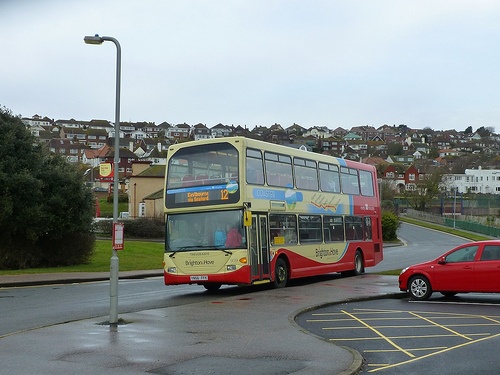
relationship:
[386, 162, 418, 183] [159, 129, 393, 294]
house behind bus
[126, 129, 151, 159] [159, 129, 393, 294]
house behind bus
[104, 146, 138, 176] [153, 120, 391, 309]
houses behind bus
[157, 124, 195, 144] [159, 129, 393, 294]
house behind bus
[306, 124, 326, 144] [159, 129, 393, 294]
house behind bus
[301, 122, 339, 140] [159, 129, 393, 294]
house behind bus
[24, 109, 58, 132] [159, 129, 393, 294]
house behind bus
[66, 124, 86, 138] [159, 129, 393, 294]
house behind bus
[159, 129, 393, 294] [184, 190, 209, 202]
bus has number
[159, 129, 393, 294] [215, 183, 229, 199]
bus has route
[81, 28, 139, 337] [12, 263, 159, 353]
pole lamp on street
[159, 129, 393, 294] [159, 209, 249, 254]
bus has window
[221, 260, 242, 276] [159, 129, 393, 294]
light front bus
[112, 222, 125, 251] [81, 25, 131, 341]
sign on pole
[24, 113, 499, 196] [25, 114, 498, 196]
houses on hill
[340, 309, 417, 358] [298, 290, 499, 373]
line on pavement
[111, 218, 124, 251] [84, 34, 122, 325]
sign attached to pole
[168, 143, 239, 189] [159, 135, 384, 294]
window on bus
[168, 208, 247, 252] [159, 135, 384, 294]
window on bus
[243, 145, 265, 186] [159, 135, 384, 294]
window on bus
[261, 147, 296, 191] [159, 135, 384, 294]
window on bus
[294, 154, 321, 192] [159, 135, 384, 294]
window on bus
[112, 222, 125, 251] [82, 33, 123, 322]
sign attached to pole lamp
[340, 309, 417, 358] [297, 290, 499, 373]
line painted on parking lot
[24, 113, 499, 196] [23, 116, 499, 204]
houses covering ridge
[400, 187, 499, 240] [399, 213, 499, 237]
fence along sidewalk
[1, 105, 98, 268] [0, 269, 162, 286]
tree near sidewalk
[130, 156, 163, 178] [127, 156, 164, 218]
roof on building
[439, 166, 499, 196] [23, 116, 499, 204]
building at bottom of ridge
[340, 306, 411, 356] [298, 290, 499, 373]
line on pavement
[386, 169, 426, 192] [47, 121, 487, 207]
building in city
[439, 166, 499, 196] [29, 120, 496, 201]
building in city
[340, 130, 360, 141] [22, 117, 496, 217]
building in city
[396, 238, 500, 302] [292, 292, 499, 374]
car on parking lot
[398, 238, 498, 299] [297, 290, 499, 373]
car parked in parking lot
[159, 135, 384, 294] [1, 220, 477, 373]
bus driving on street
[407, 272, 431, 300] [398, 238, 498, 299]
tire on car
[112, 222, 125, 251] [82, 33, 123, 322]
sign on pole lamp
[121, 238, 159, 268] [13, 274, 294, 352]
grassy area side street